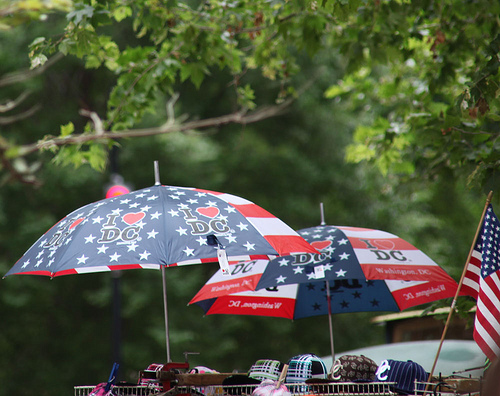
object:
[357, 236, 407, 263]
i love dc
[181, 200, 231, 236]
i love dc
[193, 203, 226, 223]
hearts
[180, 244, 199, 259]
stars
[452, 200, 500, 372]
flag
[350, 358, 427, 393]
hats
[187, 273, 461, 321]
umbrella border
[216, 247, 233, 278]
price tag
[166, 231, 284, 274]
side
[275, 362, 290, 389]
clothes pin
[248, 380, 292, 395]
hat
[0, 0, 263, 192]
trees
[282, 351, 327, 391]
hat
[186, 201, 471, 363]
umbrella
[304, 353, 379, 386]
hat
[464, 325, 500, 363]
stripes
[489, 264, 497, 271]
stars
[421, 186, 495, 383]
stick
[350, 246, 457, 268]
stripes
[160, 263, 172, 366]
pole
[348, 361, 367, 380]
designs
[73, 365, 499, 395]
cart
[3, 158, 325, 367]
umbrellas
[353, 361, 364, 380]
print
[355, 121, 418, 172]
leaves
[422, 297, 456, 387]
handle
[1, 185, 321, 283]
item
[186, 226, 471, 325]
item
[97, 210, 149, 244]
i love dc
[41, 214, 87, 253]
i love dc